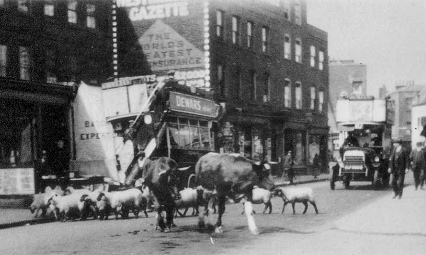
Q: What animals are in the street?
A: Cows and sheep.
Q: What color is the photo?
A: Black and white.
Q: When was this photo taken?
A: During the day.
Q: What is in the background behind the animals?
A: Buildings.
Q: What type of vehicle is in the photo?
A: Truck.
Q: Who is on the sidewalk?
A: People.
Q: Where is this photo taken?
A: In a city.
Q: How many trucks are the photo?
A: 1.